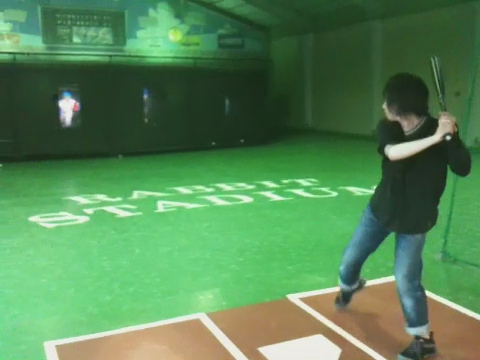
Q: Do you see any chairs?
A: No, there are no chairs.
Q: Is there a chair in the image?
A: No, there are no chairs.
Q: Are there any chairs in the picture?
A: No, there are no chairs.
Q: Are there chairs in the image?
A: No, there are no chairs.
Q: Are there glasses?
A: No, there are no glasses.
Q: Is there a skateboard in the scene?
A: No, there are no skateboards.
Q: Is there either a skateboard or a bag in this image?
A: No, there are no skateboards or bags.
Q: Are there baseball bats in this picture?
A: Yes, there is a baseball bat.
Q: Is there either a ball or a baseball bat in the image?
A: Yes, there is a baseball bat.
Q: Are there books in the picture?
A: No, there are no books.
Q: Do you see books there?
A: No, there are no books.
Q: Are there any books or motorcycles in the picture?
A: No, there are no books or motorcycles.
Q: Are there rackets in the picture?
A: No, there are no rackets.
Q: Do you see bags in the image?
A: No, there are no bags.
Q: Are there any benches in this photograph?
A: No, there are no benches.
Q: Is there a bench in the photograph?
A: No, there are no benches.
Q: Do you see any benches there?
A: No, there are no benches.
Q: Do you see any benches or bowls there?
A: No, there are no benches or bowls.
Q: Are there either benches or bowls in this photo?
A: No, there are no benches or bowls.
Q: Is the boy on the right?
A: Yes, the boy is on the right of the image.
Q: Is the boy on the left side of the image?
A: No, the boy is on the right of the image.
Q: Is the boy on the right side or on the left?
A: The boy is on the right of the image.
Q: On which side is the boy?
A: The boy is on the right of the image.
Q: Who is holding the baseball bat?
A: The boy is holding the baseball bat.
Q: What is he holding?
A: The boy is holding the baseball bat.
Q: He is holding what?
A: The boy is holding the baseball bat.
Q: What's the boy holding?
A: The boy is holding the baseball bat.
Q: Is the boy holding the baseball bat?
A: Yes, the boy is holding the baseball bat.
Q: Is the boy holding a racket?
A: No, the boy is holding the baseball bat.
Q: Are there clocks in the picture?
A: No, there are no clocks.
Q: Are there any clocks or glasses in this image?
A: No, there are no clocks or glasses.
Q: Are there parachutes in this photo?
A: No, there are no parachutes.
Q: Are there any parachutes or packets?
A: No, there are no parachutes or packets.